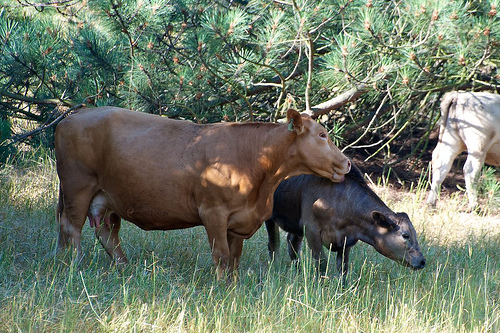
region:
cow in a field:
[420, 75, 499, 215]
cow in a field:
[30, 105, 355, 286]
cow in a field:
[257, 147, 437, 297]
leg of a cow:
[45, 163, 109, 287]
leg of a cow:
[83, 197, 140, 277]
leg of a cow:
[190, 189, 244, 294]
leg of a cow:
[212, 201, 267, 286]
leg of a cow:
[300, 225, 332, 287]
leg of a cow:
[327, 228, 357, 299]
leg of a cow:
[263, 218, 285, 276]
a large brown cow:
[47, 106, 350, 275]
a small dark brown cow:
[265, 162, 427, 270]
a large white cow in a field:
[419, 90, 499, 209]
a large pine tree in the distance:
[0, 0, 498, 192]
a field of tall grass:
[0, 145, 498, 330]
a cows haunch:
[193, 169, 245, 219]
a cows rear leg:
[49, 157, 96, 287]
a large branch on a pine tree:
[305, 78, 370, 118]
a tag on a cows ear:
[284, 113, 296, 133]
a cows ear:
[370, 210, 395, 228]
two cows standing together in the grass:
[38, 103, 424, 292]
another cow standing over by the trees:
[426, 93, 491, 210]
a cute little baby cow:
[276, 172, 429, 282]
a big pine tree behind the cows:
[4, 5, 496, 167]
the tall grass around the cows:
[8, 213, 492, 327]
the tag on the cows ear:
[283, 115, 296, 135]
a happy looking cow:
[282, 112, 356, 190]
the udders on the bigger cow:
[84, 198, 119, 234]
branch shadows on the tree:
[418, 95, 483, 152]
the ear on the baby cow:
[369, 210, 401, 233]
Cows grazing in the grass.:
[0, 105, 427, 281]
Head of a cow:
[275, 107, 353, 183]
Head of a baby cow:
[362, 208, 428, 271]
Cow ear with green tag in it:
[281, 103, 307, 138]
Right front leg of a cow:
[196, 194, 233, 275]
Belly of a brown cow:
[97, 178, 209, 235]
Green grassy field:
[92, 265, 394, 324]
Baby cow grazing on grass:
[359, 199, 442, 289]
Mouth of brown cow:
[331, 163, 348, 180]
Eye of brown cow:
[318, 130, 327, 140]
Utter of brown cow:
[87, 192, 120, 236]